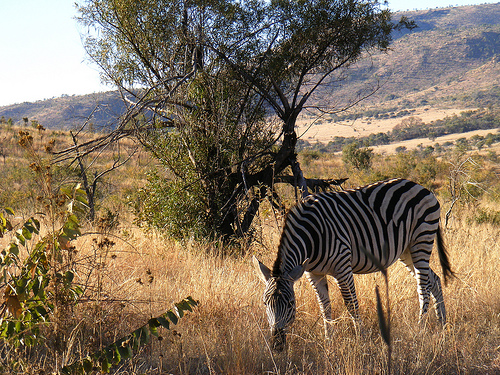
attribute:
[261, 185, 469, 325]
zebra — grazing, nature, black, white, eating, alone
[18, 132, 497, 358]
field — grass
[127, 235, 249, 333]
grass — brown, tall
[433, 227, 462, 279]
tail — black, hairy, bushy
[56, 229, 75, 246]
leaves — green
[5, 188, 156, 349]
bush — growing, green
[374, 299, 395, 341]
buds — brown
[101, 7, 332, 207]
trees — leaved, dead, bare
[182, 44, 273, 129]
leaves — green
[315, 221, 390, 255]
stripes — black, white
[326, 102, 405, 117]
trees — green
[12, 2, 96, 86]
sky — light blue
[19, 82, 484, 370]
landscape — tan, open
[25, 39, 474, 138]
background — mountainous, large